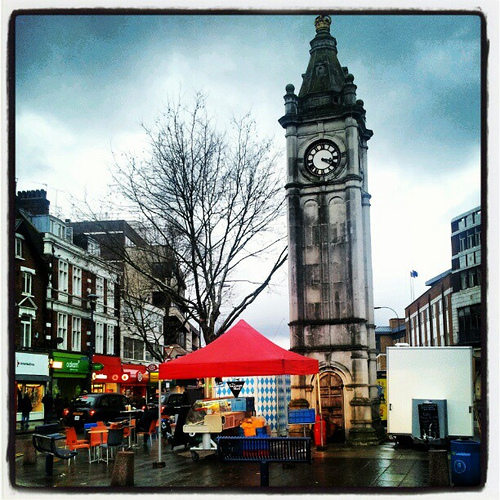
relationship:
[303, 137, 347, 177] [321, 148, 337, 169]
clock reads 3:30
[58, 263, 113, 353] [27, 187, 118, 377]
windows are on building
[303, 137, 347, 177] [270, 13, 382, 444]
clock in tower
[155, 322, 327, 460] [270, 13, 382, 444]
tent in front of tower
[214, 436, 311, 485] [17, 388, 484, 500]
bench on pavement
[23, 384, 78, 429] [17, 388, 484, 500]
people walking on pavement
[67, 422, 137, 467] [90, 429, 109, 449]
seats around a table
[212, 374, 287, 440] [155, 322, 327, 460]
wall behind tent